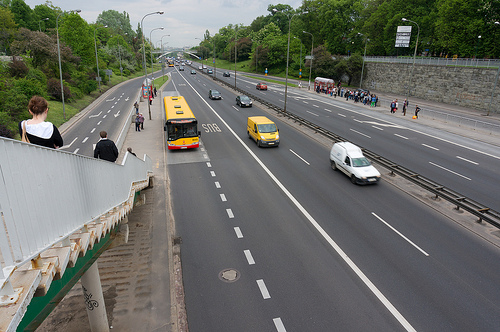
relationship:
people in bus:
[322, 78, 428, 117] [162, 93, 202, 155]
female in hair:
[18, 93, 63, 148] [26, 92, 48, 116]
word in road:
[200, 122, 220, 132] [83, 57, 498, 332]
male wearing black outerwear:
[95, 130, 120, 161] [92, 137, 117, 162]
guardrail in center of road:
[404, 166, 498, 228] [183, 75, 498, 315]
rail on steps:
[0, 134, 147, 169] [4, 121, 143, 329]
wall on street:
[361, 59, 499, 114] [206, 167, 386, 317]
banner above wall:
[391, 22, 414, 52] [338, 55, 498, 110]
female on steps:
[13, 93, 69, 175] [4, 121, 143, 329]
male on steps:
[83, 118, 128, 170] [1, 107, 160, 231]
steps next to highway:
[4, 121, 143, 329] [56, 58, 500, 314]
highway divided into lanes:
[141, 74, 474, 314] [155, 80, 410, 319]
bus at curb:
[158, 89, 202, 154] [157, 142, 192, 329]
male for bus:
[95, 130, 120, 161] [158, 89, 202, 154]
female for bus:
[18, 93, 63, 148] [158, 89, 202, 154]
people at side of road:
[414, 105, 421, 117] [83, 57, 498, 332]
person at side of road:
[402, 95, 409, 105] [83, 57, 498, 332]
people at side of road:
[401, 102, 406, 115] [83, 57, 498, 332]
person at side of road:
[388, 98, 395, 113] [83, 57, 498, 332]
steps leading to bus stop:
[4, 121, 143, 329] [121, 70, 173, 134]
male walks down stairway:
[95, 130, 120, 161] [2, 153, 152, 287]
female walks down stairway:
[18, 93, 63, 148] [2, 153, 152, 287]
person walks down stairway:
[124, 144, 139, 158] [2, 153, 152, 287]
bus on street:
[163, 95, 201, 151] [61, 59, 498, 330]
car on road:
[247, 115, 280, 148] [83, 57, 498, 332]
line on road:
[169, 60, 419, 330] [83, 57, 498, 332]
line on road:
[365, 207, 426, 255] [83, 57, 498, 332]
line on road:
[285, 143, 309, 170] [83, 57, 498, 332]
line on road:
[293, 88, 498, 163] [83, 57, 498, 332]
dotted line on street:
[202, 173, 291, 330] [168, 83, 403, 330]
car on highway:
[315, 136, 382, 192] [56, 58, 500, 314]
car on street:
[254, 79, 270, 91] [181, 55, 496, 247]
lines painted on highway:
[219, 191, 227, 201] [171, 140, 481, 328]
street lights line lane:
[44, 3, 176, 104] [173, 62, 499, 328]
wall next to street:
[361, 59, 499, 114] [61, 59, 498, 330]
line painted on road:
[198, 142, 286, 330] [83, 57, 498, 332]